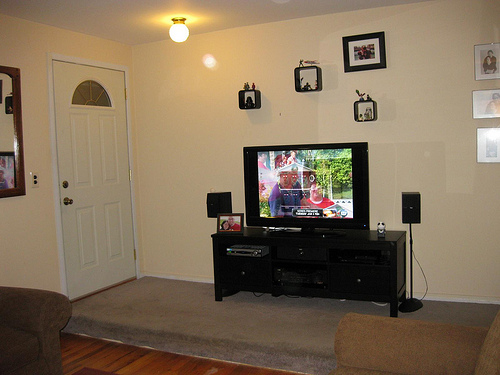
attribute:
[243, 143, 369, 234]
tv — framed in black, on, black, flat screen, large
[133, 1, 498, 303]
wall — off white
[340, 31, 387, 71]
picture frame — black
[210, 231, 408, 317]
stand — long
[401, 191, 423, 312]
speaker — small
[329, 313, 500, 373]
chair — brown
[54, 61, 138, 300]
door — white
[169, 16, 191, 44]
light — small, on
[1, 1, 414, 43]
ceiling — white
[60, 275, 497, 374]
floor — hardwood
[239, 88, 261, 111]
shelf — black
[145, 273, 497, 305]
floor trim — white